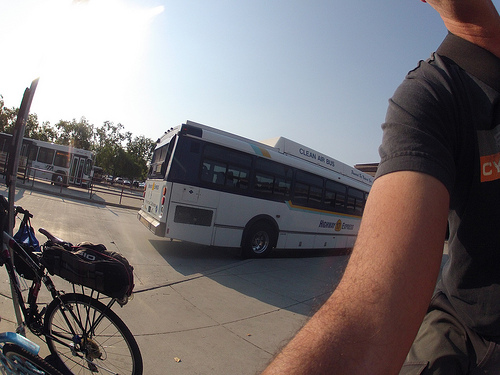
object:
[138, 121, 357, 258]
bus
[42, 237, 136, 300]
bag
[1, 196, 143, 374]
bicycle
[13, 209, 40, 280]
bike helmet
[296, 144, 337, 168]
writting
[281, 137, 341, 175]
side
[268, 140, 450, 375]
arm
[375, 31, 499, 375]
shirt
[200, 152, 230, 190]
windows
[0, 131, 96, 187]
bus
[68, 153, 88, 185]
double doors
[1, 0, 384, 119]
sky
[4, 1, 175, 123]
clouds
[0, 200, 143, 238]
road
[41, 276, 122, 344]
bracket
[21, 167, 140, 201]
railing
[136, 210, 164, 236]
bumper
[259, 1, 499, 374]
man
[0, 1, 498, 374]
day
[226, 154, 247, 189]
windows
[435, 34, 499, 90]
strap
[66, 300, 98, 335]
spokes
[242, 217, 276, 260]
wheel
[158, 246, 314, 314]
shadow